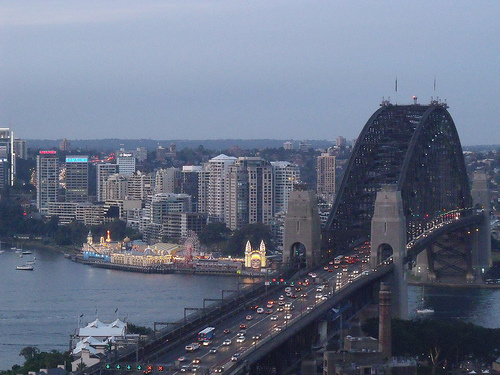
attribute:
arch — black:
[321, 100, 473, 256]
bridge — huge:
[83, 39, 499, 374]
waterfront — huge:
[78, 235, 270, 285]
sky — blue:
[8, 55, 135, 122]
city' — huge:
[25, 85, 482, 337]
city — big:
[1, 68, 498, 372]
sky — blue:
[0, 0, 485, 147]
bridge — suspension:
[135, 199, 420, 372]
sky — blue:
[126, 39, 220, 123]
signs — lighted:
[27, 142, 89, 164]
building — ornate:
[240, 226, 269, 270]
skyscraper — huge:
[221, 137, 278, 260]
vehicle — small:
[265, 311, 280, 325]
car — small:
[208, 345, 218, 354]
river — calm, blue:
[3, 245, 498, 373]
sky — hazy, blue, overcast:
[177, 40, 297, 105]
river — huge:
[3, 242, 498, 351]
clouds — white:
[23, 8, 109, 38]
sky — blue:
[161, 64, 214, 117]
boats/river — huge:
[3, 238, 45, 302]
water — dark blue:
[18, 274, 171, 315]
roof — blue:
[209, 149, 241, 170]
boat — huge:
[415, 306, 438, 313]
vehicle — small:
[242, 310, 254, 321]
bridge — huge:
[79, 102, 487, 370]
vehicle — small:
[297, 286, 307, 304]